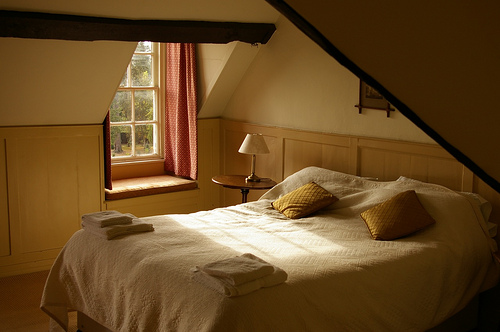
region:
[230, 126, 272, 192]
small table lamp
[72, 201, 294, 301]
two sets of folded towels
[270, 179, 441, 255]
two yellow pillows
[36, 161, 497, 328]
a white bed spread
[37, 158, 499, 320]
a bed with pillows and towels on it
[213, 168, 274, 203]
small oval side table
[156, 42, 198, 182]
red and white curtains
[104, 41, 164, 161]
a window with 8 panes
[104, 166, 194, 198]
a seat cushion under the window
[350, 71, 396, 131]
picture hanging over the bed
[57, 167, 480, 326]
a king size bed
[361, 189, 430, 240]
a gold colored pillow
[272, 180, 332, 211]
a gold colored pillow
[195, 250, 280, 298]
a stack of towels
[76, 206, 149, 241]
a stack of towels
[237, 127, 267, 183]
a small table lamp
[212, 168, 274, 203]
a wooden bedside table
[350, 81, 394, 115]
a framed wall picture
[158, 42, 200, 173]
a red curtain panel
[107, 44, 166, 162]
a white paned window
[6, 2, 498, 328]
A bedroom.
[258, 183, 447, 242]
Beige colored small pillows.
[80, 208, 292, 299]
Two stacks of towels at the end of the bed.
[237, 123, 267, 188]
A small light colored lamp.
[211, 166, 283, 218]
A round wooden nightstand.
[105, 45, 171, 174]
A window.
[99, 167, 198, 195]
A built in bench under the window.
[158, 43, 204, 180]
Red curtains hanging.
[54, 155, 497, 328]
A bed with a white comforter on it.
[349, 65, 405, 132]
A picture hanging on the wall.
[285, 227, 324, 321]
the bed is white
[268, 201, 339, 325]
the bed is white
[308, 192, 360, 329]
the bed is white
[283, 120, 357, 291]
the bed is white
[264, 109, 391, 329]
the bed is white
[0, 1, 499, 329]
fairly nice hotel bedroom with @ least one angled wall. might be something like air b&b.....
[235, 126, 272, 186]
tiny lamp on nightstand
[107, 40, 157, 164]
nice view of greenery from eight paneled window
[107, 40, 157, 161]
window has 8 panels but only 5 are totally visible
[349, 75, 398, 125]
an unusual extended end frame on small picture over bed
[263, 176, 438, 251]
two square goldish green pillows laid out diamond shape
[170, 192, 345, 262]
the sun from the window shining down on the bed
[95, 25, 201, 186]
two red-orange curtains with, i think, little cream colour dots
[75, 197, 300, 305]
four towels of two types stacked @ bed's end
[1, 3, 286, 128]
an angled wall probably created by a gabled roof